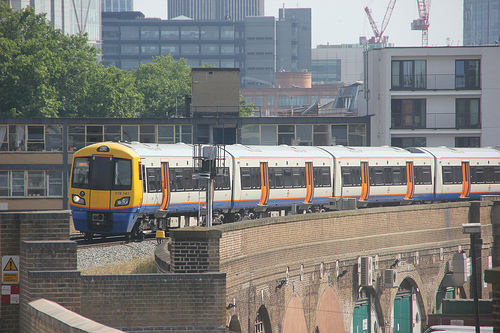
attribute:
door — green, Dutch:
[393, 291, 412, 331]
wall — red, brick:
[170, 238, 219, 272]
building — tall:
[3, 0, 103, 61]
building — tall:
[103, 0, 133, 13]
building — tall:
[102, 10, 243, 85]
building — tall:
[165, 1, 264, 19]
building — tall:
[276, 4, 311, 71]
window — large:
[390, 58, 401, 89]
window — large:
[390, 95, 403, 128]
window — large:
[400, 97, 415, 128]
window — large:
[455, 96, 471, 127]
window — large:
[413, 60, 426, 89]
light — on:
[70, 194, 81, 203]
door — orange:
[160, 161, 170, 210]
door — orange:
[255, 160, 269, 205]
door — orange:
[303, 159, 313, 202]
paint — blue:
[70, 202, 141, 235]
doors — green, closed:
[352, 284, 414, 330]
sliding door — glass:
[392, 60, 424, 86]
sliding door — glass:
[456, 59, 481, 86]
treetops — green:
[4, 6, 185, 113]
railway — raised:
[16, 203, 498, 330]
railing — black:
[393, 70, 481, 89]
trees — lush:
[4, 7, 188, 113]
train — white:
[65, 130, 497, 243]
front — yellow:
[61, 137, 140, 234]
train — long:
[68, 138, 498, 236]